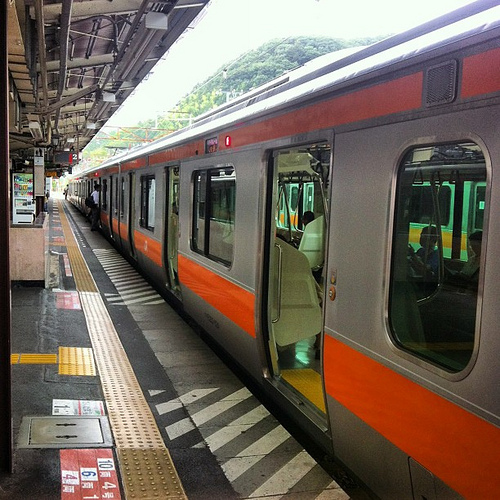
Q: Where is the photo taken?
A: At the train station.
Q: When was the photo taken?
A: During the day.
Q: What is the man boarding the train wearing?
A: A white shirt and dark pants.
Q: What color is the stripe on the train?
A: Orange.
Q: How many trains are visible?
A: Two.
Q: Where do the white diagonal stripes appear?
A: On the train platform.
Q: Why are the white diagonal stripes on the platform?
A: To denote where the train doors will be.